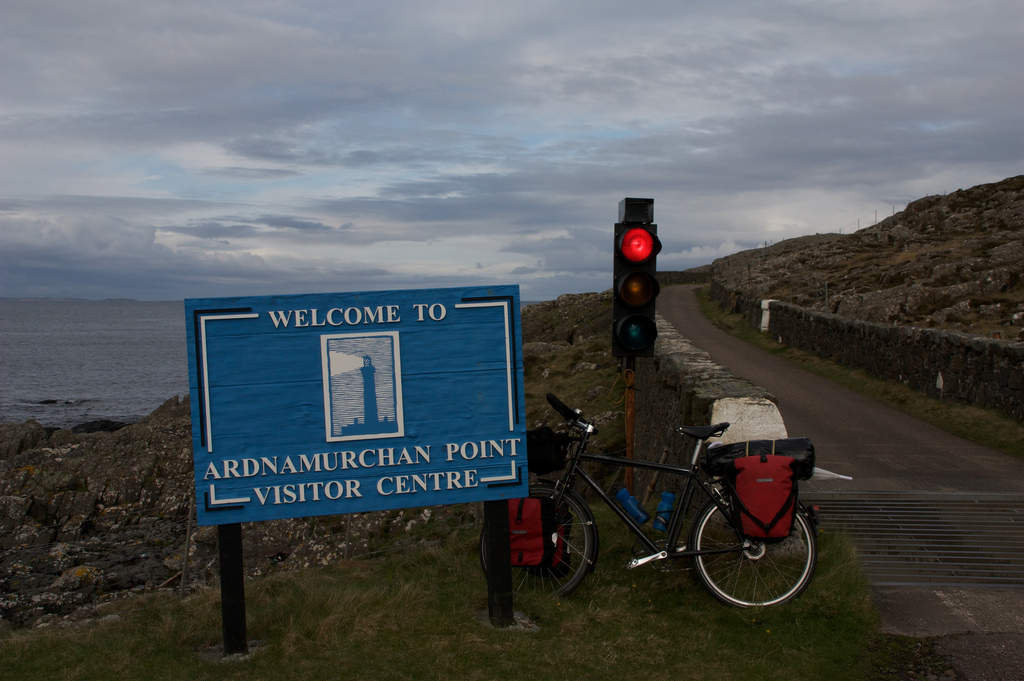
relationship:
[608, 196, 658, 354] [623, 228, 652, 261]
traffic light shining red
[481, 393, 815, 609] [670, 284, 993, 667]
bicycle parked on side of road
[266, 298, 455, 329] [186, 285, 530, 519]
white writing on blue background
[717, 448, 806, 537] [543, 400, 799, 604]
bag attached to bicycle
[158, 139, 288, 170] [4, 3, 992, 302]
cloud hanging in sky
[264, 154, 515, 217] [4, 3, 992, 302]
cloud hanging in sky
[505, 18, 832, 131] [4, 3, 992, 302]
cloud hanging in sky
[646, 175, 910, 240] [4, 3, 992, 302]
cloud hanging in sky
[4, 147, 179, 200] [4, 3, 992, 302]
cloud hanging in sky